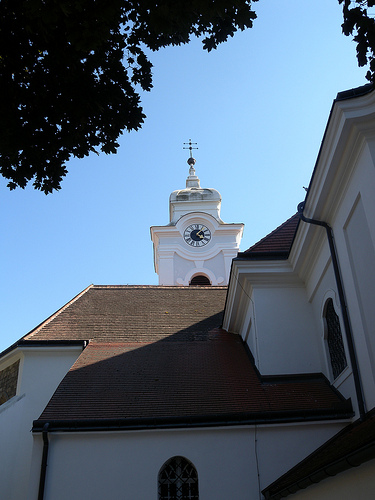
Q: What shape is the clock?
A: Round.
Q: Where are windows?
A: On the building.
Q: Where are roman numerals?
A: On the clock.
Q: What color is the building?
A: White.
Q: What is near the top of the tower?
A: A clock.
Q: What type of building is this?
A: A church.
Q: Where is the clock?
A: On the tower.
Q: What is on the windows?
A: Glass and metals.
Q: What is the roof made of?
A: Shingles.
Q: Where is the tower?
A: Behind the roof.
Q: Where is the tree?
A: Next to the building.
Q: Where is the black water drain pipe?
A: On the building.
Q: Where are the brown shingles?
A: On the roof.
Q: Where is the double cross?
A: On top of the clock tower.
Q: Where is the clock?
A: On the tower.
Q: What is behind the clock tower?
A: Sky.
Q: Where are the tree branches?
A: Top left of the picture.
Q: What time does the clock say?
A: 4:05.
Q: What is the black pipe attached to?
A: The building.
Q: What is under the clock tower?
A: Roof.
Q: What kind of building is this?
A: A church.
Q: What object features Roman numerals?
A: The clock.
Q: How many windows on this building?
A: 4.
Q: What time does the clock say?
A: 4:05.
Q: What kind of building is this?
A: Church.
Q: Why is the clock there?
A: To tell time.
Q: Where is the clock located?
A: On the tower.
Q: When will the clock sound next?
A: 4:15.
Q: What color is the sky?
A: Blue.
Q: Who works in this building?
A: Priest.